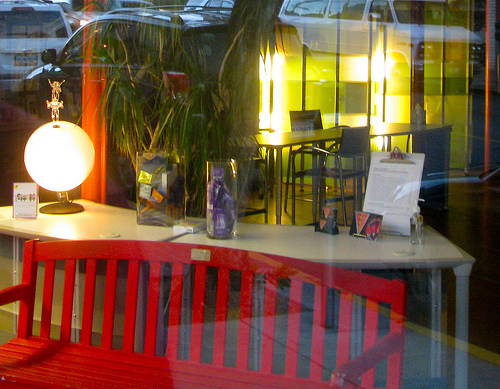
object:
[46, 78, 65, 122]
object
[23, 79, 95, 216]
lamp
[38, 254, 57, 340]
slat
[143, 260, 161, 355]
slat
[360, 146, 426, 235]
clip board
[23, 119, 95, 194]
lamp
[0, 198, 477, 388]
counter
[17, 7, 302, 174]
reflection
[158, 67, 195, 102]
tail light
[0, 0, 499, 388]
window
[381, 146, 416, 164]
silver clip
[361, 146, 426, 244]
board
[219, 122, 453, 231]
desk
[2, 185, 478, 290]
table top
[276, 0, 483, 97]
reflection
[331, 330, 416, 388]
wooden arm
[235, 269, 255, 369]
slat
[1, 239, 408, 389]
red bench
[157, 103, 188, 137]
leaves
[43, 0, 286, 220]
plant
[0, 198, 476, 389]
table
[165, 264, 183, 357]
slat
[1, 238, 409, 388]
bench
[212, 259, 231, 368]
slat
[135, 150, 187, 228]
vase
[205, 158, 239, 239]
jar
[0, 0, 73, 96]
car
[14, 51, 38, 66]
license plate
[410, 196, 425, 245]
sanitizer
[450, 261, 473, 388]
table leg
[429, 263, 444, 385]
table leg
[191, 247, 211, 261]
sign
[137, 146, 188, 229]
object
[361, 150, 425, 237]
paper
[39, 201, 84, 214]
stand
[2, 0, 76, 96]
van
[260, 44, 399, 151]
light